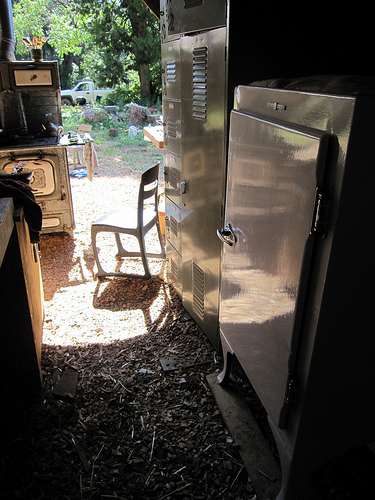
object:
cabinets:
[158, 0, 233, 355]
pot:
[45, 122, 64, 137]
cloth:
[83, 137, 97, 178]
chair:
[90, 161, 167, 283]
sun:
[47, 177, 164, 344]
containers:
[218, 76, 374, 492]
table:
[56, 132, 95, 183]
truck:
[59, 79, 116, 105]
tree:
[76, 0, 164, 108]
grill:
[74, 97, 86, 106]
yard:
[61, 95, 165, 185]